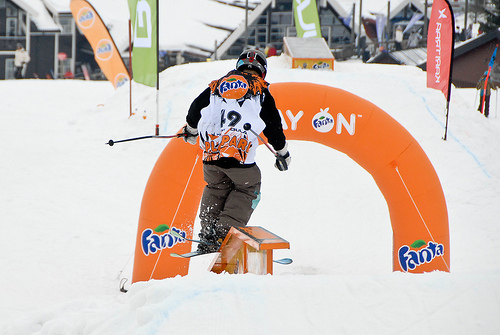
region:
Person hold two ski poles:
[171, 33, 298, 273]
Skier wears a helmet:
[171, 39, 315, 264]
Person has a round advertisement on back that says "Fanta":
[210, 67, 252, 105]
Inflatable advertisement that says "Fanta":
[120, 78, 461, 283]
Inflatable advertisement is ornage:
[121, 71, 459, 290]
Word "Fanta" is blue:
[390, 235, 450, 275]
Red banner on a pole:
[418, 0, 463, 142]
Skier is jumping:
[158, 38, 315, 278]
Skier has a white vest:
[160, 36, 303, 272]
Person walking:
[7, 36, 37, 86]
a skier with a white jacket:
[2, 33, 41, 142]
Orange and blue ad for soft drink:
[350, 159, 465, 281]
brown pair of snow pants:
[175, 144, 291, 262]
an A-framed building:
[211, 0, 402, 91]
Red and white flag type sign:
[411, 4, 457, 121]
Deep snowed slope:
[370, 42, 498, 251]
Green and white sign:
[120, 7, 174, 134]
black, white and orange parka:
[169, 69, 299, 174]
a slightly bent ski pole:
[78, 119, 198, 151]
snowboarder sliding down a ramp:
[72, 11, 447, 303]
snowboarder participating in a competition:
[81, 55, 452, 287]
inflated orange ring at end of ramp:
[116, 60, 456, 281]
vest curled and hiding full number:
[141, 67, 281, 167]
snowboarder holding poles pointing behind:
[101, 102, 306, 167]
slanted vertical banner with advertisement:
[55, 10, 126, 106]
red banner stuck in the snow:
[411, 5, 466, 160]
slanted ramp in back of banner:
[251, 12, 362, 72]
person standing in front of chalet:
[2, 12, 57, 92]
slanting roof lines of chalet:
[211, 1, 378, 62]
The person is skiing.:
[94, 49, 301, 283]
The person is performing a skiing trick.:
[91, 40, 314, 265]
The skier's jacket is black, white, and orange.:
[180, 70, 289, 170]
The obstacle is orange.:
[302, 77, 454, 282]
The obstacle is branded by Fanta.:
[390, 232, 456, 279]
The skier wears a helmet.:
[230, 39, 275, 76]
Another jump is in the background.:
[275, 32, 340, 78]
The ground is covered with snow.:
[3, 84, 142, 334]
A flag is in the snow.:
[407, 0, 459, 142]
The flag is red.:
[411, 0, 459, 147]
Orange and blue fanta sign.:
[207, 64, 252, 125]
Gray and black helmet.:
[220, 30, 276, 81]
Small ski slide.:
[135, 200, 339, 321]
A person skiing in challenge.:
[158, 33, 315, 333]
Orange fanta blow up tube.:
[55, 78, 484, 275]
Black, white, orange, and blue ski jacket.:
[169, 81, 289, 186]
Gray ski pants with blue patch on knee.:
[168, 158, 273, 311]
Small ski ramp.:
[281, 12, 368, 80]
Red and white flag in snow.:
[400, 5, 477, 164]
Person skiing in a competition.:
[93, 17, 466, 307]